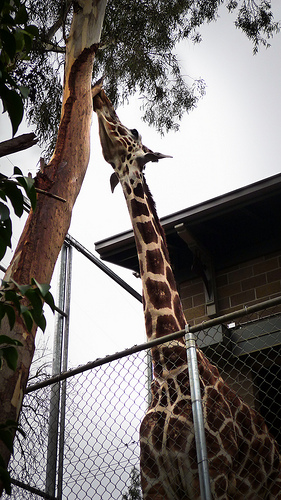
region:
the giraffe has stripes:
[89, 341, 270, 478]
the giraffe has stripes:
[67, 286, 229, 498]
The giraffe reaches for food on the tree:
[80, 66, 212, 340]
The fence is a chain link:
[110, 399, 157, 481]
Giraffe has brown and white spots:
[211, 419, 237, 471]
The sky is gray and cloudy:
[70, 283, 109, 329]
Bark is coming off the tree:
[45, 164, 61, 265]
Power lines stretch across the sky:
[71, 441, 146, 484]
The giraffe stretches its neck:
[108, 138, 195, 354]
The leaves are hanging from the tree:
[112, 12, 209, 127]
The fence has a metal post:
[178, 330, 214, 498]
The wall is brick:
[220, 263, 267, 311]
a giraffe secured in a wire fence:
[92, 91, 279, 498]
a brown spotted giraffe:
[92, 89, 279, 498]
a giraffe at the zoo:
[0, 0, 280, 498]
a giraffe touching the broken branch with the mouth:
[92, 75, 279, 498]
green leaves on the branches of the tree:
[0, 0, 54, 370]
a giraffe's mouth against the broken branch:
[91, 74, 112, 110]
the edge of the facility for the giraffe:
[94, 172, 280, 439]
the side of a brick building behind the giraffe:
[92, 172, 278, 407]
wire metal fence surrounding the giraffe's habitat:
[1, 296, 280, 498]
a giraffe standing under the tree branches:
[0, 89, 279, 499]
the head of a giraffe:
[88, 83, 174, 192]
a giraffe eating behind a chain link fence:
[26, 83, 279, 498]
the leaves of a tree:
[0, 2, 54, 449]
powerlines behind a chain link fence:
[60, 437, 139, 487]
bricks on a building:
[222, 264, 276, 294]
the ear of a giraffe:
[139, 148, 173, 165]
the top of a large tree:
[0, 0, 280, 70]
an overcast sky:
[211, 55, 280, 171]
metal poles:
[50, 240, 76, 374]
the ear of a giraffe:
[109, 168, 120, 193]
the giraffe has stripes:
[90, 328, 247, 497]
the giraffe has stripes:
[136, 362, 205, 487]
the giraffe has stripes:
[93, 226, 241, 465]